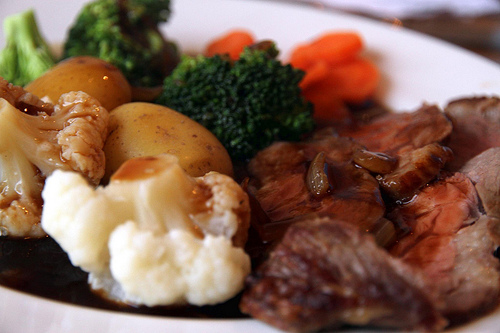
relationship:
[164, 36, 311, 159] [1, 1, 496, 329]
broccoli on plate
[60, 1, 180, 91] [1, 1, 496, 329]
broccoli on plate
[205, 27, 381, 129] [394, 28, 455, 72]
carrots on plate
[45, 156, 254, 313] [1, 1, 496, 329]
cauliflower on plate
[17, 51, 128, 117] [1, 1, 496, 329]
potato on plate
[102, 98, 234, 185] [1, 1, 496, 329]
potato on plate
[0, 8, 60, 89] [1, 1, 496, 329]
broccoli on plate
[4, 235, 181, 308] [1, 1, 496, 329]
sauce on plate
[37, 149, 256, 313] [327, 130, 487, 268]
cauliflower next to meat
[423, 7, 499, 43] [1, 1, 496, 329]
table next to plate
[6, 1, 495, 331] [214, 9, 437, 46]
food on plate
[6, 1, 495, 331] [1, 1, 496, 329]
food on plate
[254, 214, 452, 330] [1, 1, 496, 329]
beef on plate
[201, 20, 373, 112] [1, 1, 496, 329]
carrots on plate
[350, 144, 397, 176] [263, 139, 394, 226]
mushroom on steak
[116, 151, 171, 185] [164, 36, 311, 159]
mushroom gravy on broccoli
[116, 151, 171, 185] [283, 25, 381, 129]
mushroom gravy on carrots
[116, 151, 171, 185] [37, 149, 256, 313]
mushroom gravy on cauliflower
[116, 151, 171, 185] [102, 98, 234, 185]
mushroom gravy on potato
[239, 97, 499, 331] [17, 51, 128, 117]
beef stew and potato